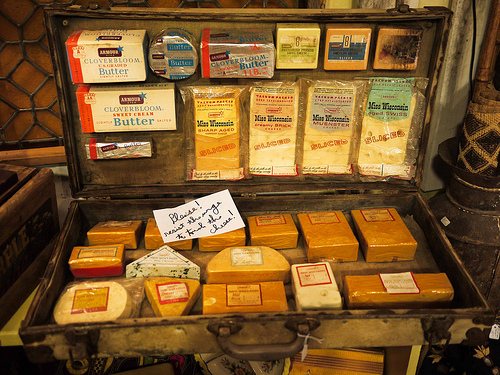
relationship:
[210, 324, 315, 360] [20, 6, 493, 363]
handle on luggage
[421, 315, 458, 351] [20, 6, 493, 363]
buckle on luggage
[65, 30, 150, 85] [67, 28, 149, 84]
butter in a box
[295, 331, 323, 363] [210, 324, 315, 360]
tag on handle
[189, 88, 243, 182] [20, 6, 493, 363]
cheese in luggage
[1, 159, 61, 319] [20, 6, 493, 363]
box next to luggage